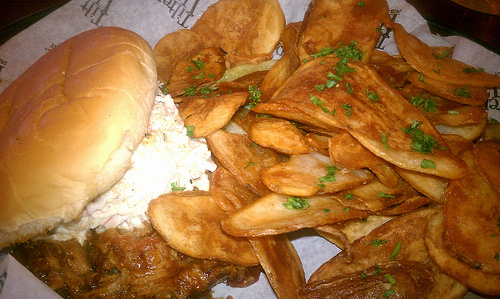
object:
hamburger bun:
[0, 27, 262, 298]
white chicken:
[39, 88, 217, 244]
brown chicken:
[98, 245, 200, 296]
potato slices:
[256, 151, 371, 196]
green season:
[335, 43, 362, 59]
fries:
[173, 88, 253, 138]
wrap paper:
[0, 0, 499, 299]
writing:
[77, 0, 114, 26]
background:
[0, 0, 499, 57]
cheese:
[154, 29, 211, 90]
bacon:
[295, 260, 436, 299]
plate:
[2, 0, 500, 58]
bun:
[2, 25, 153, 246]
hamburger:
[0, 25, 220, 250]